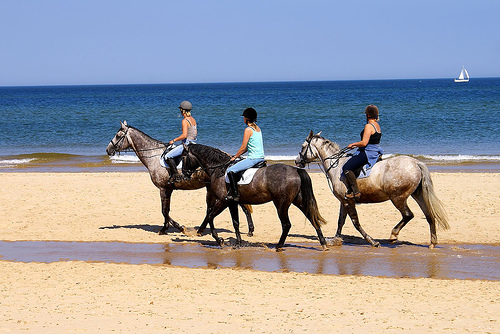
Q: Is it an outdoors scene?
A: Yes, it is outdoors.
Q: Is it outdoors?
A: Yes, it is outdoors.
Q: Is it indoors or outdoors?
A: It is outdoors.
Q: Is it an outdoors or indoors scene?
A: It is outdoors.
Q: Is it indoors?
A: No, it is outdoors.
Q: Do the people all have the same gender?
A: Yes, all the people are female.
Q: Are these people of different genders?
A: No, all the people are female.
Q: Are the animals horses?
A: Yes, all the animals are horses.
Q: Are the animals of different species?
A: No, all the animals are horses.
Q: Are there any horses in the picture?
A: Yes, there is a horse.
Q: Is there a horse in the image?
A: Yes, there is a horse.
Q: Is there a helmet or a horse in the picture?
A: Yes, there is a horse.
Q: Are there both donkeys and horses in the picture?
A: No, there is a horse but no donkeys.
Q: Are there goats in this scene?
A: No, there are no goats.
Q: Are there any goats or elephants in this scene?
A: No, there are no goats or elephants.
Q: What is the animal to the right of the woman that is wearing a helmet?
A: The animal is a horse.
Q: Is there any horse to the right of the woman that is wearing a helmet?
A: Yes, there is a horse to the right of the woman.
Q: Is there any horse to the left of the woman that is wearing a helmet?
A: No, the horse is to the right of the woman.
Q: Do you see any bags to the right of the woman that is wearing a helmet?
A: No, there is a horse to the right of the woman.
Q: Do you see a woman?
A: Yes, there is a woman.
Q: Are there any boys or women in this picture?
A: Yes, there is a woman.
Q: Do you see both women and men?
A: No, there is a woman but no men.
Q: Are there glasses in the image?
A: No, there are no glasses.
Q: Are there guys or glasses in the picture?
A: No, there are no glasses or guys.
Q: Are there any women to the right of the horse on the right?
A: No, the woman is to the left of the horse.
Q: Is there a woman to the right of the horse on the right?
A: No, the woman is to the left of the horse.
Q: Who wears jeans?
A: The woman wears jeans.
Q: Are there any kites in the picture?
A: No, there are no kites.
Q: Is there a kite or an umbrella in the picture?
A: No, there are no kites or umbrellas.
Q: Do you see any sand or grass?
A: Yes, there is sand.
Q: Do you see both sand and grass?
A: No, there is sand but no grass.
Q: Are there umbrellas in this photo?
A: No, there are no umbrellas.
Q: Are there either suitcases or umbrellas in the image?
A: No, there are no umbrellas or suitcases.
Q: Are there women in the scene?
A: Yes, there is a woman.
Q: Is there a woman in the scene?
A: Yes, there is a woman.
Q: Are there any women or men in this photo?
A: Yes, there is a woman.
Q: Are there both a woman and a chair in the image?
A: No, there is a woman but no chairs.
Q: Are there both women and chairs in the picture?
A: No, there is a woman but no chairs.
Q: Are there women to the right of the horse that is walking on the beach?
A: Yes, there is a woman to the right of the horse.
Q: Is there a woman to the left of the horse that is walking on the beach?
A: No, the woman is to the right of the horse.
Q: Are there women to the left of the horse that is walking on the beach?
A: No, the woman is to the right of the horse.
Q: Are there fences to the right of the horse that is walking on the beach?
A: No, there is a woman to the right of the horse.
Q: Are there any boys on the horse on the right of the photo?
A: No, there is a woman on the horse.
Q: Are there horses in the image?
A: Yes, there is a horse.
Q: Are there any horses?
A: Yes, there is a horse.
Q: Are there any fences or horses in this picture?
A: Yes, there is a horse.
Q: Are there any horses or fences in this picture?
A: Yes, there is a horse.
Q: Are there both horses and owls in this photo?
A: No, there is a horse but no owls.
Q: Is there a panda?
A: No, there are no pandas.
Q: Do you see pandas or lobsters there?
A: No, there are no pandas or lobsters.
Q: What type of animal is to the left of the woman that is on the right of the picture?
A: The animal is a horse.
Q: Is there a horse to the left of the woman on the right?
A: Yes, there is a horse to the left of the woman.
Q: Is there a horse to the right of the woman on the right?
A: No, the horse is to the left of the woman.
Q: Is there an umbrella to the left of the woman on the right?
A: No, there is a horse to the left of the woman.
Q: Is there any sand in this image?
A: Yes, there is sand.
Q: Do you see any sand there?
A: Yes, there is sand.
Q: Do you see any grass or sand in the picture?
A: Yes, there is sand.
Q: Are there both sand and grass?
A: No, there is sand but no grass.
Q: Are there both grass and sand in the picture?
A: No, there is sand but no grass.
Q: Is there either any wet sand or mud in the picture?
A: Yes, there is wet sand.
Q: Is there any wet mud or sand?
A: Yes, there is wet sand.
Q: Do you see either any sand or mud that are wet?
A: Yes, the sand is wet.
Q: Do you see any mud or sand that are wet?
A: Yes, the sand is wet.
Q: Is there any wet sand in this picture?
A: Yes, there is wet sand.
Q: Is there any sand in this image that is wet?
A: Yes, there is sand that is wet.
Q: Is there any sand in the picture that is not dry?
A: Yes, there is wet sand.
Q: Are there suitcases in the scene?
A: No, there are no suitcases.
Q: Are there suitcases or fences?
A: No, there are no suitcases or fences.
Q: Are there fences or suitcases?
A: No, there are no suitcases or fences.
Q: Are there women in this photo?
A: Yes, there is a woman.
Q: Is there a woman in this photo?
A: Yes, there is a woman.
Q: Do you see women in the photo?
A: Yes, there is a woman.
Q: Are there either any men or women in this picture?
A: Yes, there is a woman.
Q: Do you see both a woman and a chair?
A: No, there is a woman but no chairs.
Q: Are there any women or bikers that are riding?
A: Yes, the woman is riding.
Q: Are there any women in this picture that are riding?
A: Yes, there is a woman that is riding.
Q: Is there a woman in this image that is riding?
A: Yes, there is a woman that is riding.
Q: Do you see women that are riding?
A: Yes, there is a woman that is riding.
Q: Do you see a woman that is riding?
A: Yes, there is a woman that is riding.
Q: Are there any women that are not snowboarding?
A: Yes, there is a woman that is riding.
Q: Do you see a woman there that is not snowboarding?
A: Yes, there is a woman that is riding .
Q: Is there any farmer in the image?
A: No, there are no farmers.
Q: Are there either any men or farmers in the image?
A: No, there are no farmers or men.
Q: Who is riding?
A: The woman is riding.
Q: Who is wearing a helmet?
A: The woman is wearing a helmet.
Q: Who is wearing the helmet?
A: The woman is wearing a helmet.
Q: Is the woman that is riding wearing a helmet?
A: Yes, the woman is wearing a helmet.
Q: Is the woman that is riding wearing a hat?
A: No, the woman is wearing a helmet.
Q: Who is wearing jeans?
A: The woman is wearing jeans.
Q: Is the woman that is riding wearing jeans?
A: Yes, the woman is wearing jeans.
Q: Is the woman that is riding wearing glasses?
A: No, the woman is wearing jeans.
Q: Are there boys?
A: No, there are no boys.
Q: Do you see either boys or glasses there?
A: No, there are no boys or glasses.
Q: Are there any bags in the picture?
A: No, there are no bags.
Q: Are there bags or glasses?
A: No, there are no bags or glasses.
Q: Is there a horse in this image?
A: Yes, there is a horse.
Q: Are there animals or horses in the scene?
A: Yes, there is a horse.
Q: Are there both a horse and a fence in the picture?
A: No, there is a horse but no fences.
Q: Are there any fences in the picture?
A: No, there are no fences.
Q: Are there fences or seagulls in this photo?
A: No, there are no fences or seagulls.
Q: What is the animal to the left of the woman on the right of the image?
A: The animal is a horse.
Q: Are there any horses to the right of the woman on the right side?
A: No, the horse is to the left of the woman.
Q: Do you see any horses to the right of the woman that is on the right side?
A: No, the horse is to the left of the woman.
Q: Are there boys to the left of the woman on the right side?
A: No, there is a horse to the left of the woman.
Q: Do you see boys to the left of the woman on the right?
A: No, there is a horse to the left of the woman.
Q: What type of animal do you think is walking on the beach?
A: The animal is a horse.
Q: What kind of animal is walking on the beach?
A: The animal is a horse.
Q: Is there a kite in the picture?
A: No, there are no kites.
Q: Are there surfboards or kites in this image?
A: No, there are no kites or surfboards.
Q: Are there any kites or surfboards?
A: No, there are no kites or surfboards.